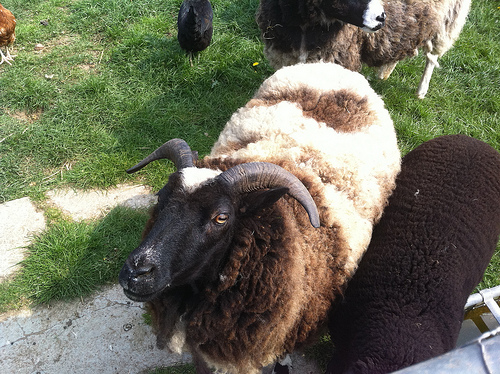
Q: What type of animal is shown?
A: Sheep.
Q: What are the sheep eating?
A: Grass.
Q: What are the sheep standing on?
A: Grass.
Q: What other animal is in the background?
A: Chickens.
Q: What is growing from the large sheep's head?
A: Horns.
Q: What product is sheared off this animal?
A: Wool.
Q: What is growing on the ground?
A: Grass.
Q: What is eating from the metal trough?
A: Sheep.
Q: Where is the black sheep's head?
A: In feeding trough.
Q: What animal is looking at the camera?
A: Sheep.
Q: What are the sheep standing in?
A: Grass.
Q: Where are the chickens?
A: Next to the sheep.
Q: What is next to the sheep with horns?
A: Black sheep.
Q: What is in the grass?
A: Stones.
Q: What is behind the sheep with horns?
A: More sheep.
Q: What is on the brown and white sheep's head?
A: Horns.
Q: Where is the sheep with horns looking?
A: At the camera.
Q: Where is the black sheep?
A: Next to the sheep with horns.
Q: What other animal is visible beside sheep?
A: Chickens.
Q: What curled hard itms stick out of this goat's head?
A: Horns.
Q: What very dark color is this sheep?
A: Black.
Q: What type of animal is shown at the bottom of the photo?
A: Sheep.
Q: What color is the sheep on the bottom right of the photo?
A: Black.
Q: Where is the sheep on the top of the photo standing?
A: In grass.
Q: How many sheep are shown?
A: Three.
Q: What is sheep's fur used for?
A: Wool.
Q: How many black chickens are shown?
A: One.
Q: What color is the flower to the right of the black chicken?
A: Yellow.